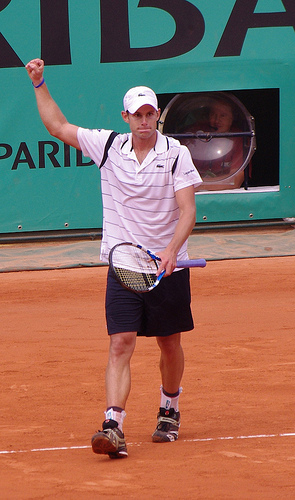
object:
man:
[26, 43, 204, 461]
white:
[84, 132, 103, 156]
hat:
[121, 80, 159, 116]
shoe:
[150, 395, 183, 445]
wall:
[0, 0, 295, 78]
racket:
[107, 238, 209, 294]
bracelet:
[28, 76, 48, 91]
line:
[2, 430, 293, 455]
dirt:
[0, 458, 294, 499]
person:
[177, 91, 247, 193]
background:
[0, 0, 295, 238]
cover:
[0, 0, 295, 241]